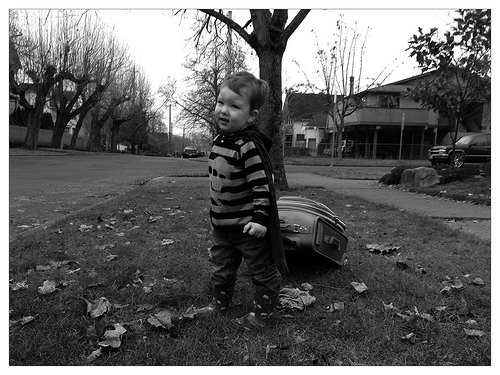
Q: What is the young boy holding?
A: Luggage.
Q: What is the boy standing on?
A: Grass.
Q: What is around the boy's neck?
A: Cape.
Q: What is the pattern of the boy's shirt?
A: Stripes.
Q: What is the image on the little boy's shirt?
A: Skull and crossbones.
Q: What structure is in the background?
A: Homes.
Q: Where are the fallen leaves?
A: On the ground.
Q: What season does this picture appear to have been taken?
A: Fall.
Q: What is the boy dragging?
A: Suitcase.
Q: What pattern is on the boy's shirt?
A: Stripes.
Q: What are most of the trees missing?
A: Leaves.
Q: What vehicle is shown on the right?
A: SUV.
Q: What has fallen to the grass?
A: Leaves.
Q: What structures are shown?
A: Houses.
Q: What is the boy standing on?
A: Grass.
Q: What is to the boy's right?
A: Street.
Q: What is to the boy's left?
A: Sidewalk.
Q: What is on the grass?
A: A suitcase.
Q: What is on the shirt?
A: Strip colors.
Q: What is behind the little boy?
A: A tree.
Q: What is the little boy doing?
A: Pulling a suitcase.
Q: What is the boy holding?
A: A suitcase.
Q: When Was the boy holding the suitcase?
A: Daytime.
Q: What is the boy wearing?
A: A striped sweater.